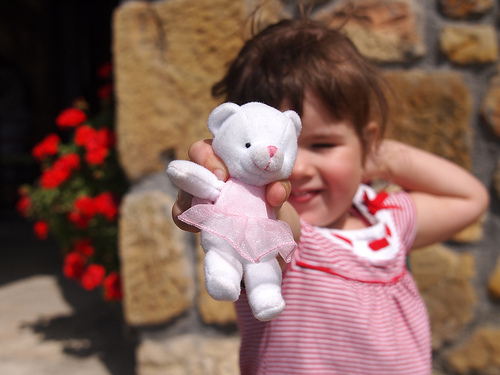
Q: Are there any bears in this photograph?
A: Yes, there is a bear.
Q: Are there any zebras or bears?
A: Yes, there is a bear.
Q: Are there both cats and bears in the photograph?
A: No, there is a bear but no cats.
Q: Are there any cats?
A: No, there are no cats.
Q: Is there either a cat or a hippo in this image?
A: No, there are no cats or hippos.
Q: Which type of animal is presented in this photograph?
A: The animal is a bear.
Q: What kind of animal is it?
A: The animal is a bear.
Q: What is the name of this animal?
A: This is a bear.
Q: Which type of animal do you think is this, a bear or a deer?
A: This is a bear.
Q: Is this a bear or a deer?
A: This is a bear.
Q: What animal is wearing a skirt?
A: The bear is wearing a skirt.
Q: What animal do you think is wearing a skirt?
A: The animal is a bear.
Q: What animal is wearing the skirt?
A: The animal is a bear.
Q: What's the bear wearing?
A: The bear is wearing a skirt.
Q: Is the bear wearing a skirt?
A: Yes, the bear is wearing a skirt.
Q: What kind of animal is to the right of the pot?
A: The animal is a bear.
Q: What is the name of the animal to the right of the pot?
A: The animal is a bear.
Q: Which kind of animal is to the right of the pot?
A: The animal is a bear.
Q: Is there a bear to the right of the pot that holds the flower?
A: Yes, there is a bear to the right of the pot.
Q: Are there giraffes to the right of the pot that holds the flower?
A: No, there is a bear to the right of the pot.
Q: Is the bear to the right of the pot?
A: Yes, the bear is to the right of the pot.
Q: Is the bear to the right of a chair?
A: No, the bear is to the right of the pot.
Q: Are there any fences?
A: No, there are no fences.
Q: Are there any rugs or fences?
A: No, there are no fences or rugs.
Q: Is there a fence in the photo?
A: No, there are no fences.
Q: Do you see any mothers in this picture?
A: No, there are no mothers.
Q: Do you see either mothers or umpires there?
A: No, there are no mothers or umpires.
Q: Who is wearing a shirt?
A: The girl is wearing a shirt.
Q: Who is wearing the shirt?
A: The girl is wearing a shirt.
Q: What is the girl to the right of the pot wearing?
A: The girl is wearing a shirt.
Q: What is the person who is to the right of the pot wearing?
A: The girl is wearing a shirt.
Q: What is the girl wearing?
A: The girl is wearing a shirt.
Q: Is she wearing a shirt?
A: Yes, the girl is wearing a shirt.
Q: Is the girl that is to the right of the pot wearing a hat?
A: No, the girl is wearing a shirt.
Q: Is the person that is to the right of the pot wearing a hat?
A: No, the girl is wearing a shirt.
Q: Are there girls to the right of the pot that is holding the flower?
A: Yes, there is a girl to the right of the pot.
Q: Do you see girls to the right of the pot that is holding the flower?
A: Yes, there is a girl to the right of the pot.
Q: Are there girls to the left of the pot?
A: No, the girl is to the right of the pot.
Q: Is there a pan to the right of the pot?
A: No, there is a girl to the right of the pot.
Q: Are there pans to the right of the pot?
A: No, there is a girl to the right of the pot.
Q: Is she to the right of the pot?
A: Yes, the girl is to the right of the pot.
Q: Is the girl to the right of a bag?
A: No, the girl is to the right of the pot.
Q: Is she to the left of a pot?
A: No, the girl is to the right of a pot.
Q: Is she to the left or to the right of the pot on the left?
A: The girl is to the right of the pot.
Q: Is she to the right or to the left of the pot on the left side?
A: The girl is to the right of the pot.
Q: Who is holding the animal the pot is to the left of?
A: The girl is holding the bear.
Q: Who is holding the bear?
A: The girl is holding the bear.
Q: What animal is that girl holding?
A: The girl is holding the bear.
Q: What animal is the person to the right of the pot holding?
A: The girl is holding the bear.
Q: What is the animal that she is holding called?
A: The animal is a bear.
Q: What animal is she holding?
A: The girl is holding the bear.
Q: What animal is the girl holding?
A: The girl is holding the bear.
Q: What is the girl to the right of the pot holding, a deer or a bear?
A: The girl is holding a bear.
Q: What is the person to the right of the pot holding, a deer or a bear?
A: The girl is holding a bear.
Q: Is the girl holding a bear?
A: Yes, the girl is holding a bear.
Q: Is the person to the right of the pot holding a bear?
A: Yes, the girl is holding a bear.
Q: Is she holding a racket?
A: No, the girl is holding a bear.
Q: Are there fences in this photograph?
A: No, there are no fences.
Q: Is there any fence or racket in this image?
A: No, there are no fences or rackets.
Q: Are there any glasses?
A: No, there are no glasses.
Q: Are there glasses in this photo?
A: No, there are no glasses.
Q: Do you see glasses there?
A: No, there are no glasses.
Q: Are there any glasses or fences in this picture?
A: No, there are no glasses or fences.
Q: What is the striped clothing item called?
A: The clothing item is a shirt.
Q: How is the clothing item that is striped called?
A: The clothing item is a shirt.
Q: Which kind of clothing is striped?
A: The clothing is a shirt.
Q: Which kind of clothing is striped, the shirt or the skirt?
A: The shirt is striped.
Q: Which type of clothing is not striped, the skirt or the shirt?
A: The skirt is not striped.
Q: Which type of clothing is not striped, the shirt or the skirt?
A: The skirt is not striped.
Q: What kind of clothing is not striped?
A: The clothing is a skirt.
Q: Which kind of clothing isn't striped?
A: The clothing is a skirt.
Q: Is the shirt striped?
A: Yes, the shirt is striped.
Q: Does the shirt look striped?
A: Yes, the shirt is striped.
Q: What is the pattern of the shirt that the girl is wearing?
A: The shirt is striped.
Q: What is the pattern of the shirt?
A: The shirt is striped.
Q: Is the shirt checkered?
A: No, the shirt is striped.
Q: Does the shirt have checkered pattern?
A: No, the shirt is striped.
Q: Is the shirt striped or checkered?
A: The shirt is striped.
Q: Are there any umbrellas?
A: No, there are no umbrellas.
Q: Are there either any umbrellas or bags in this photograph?
A: No, there are no umbrellas or bags.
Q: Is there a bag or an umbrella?
A: No, there are no umbrellas or bags.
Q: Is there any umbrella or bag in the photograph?
A: No, there are no umbrellas or bags.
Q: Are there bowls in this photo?
A: No, there are no bowls.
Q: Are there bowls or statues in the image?
A: No, there are no bowls or statues.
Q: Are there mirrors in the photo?
A: No, there are no mirrors.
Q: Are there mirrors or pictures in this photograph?
A: No, there are no mirrors or pictures.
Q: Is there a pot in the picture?
A: Yes, there is a pot.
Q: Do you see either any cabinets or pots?
A: Yes, there is a pot.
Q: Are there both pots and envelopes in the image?
A: No, there is a pot but no envelopes.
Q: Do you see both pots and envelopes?
A: No, there is a pot but no envelopes.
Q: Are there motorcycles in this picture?
A: No, there are no motorcycles.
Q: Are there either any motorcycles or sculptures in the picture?
A: No, there are no motorcycles or sculptures.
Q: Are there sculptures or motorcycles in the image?
A: No, there are no motorcycles or sculptures.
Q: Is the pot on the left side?
A: Yes, the pot is on the left of the image.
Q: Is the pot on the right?
A: No, the pot is on the left of the image.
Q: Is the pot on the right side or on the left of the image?
A: The pot is on the left of the image.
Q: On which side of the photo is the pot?
A: The pot is on the left of the image.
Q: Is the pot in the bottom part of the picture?
A: Yes, the pot is in the bottom of the image.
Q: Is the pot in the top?
A: No, the pot is in the bottom of the image.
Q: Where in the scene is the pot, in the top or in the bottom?
A: The pot is in the bottom of the image.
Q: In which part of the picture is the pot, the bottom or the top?
A: The pot is in the bottom of the image.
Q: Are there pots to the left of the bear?
A: Yes, there is a pot to the left of the bear.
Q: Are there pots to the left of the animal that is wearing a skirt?
A: Yes, there is a pot to the left of the bear.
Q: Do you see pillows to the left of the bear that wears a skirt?
A: No, there is a pot to the left of the bear.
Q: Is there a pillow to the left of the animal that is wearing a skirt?
A: No, there is a pot to the left of the bear.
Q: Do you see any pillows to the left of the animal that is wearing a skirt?
A: No, there is a pot to the left of the bear.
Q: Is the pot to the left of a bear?
A: Yes, the pot is to the left of a bear.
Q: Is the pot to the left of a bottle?
A: No, the pot is to the left of a bear.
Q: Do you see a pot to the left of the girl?
A: Yes, there is a pot to the left of the girl.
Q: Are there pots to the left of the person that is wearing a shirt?
A: Yes, there is a pot to the left of the girl.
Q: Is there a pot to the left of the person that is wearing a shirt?
A: Yes, there is a pot to the left of the girl.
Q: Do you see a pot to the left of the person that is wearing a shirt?
A: Yes, there is a pot to the left of the girl.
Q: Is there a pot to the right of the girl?
A: No, the pot is to the left of the girl.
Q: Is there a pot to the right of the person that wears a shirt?
A: No, the pot is to the left of the girl.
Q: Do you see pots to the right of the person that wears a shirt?
A: No, the pot is to the left of the girl.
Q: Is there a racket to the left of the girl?
A: No, there is a pot to the left of the girl.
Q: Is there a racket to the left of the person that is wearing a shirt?
A: No, there is a pot to the left of the girl.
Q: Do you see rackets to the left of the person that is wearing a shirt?
A: No, there is a pot to the left of the girl.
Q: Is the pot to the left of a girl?
A: Yes, the pot is to the left of a girl.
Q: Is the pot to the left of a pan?
A: No, the pot is to the left of a girl.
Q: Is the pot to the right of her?
A: No, the pot is to the left of the girl.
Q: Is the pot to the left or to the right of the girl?
A: The pot is to the left of the girl.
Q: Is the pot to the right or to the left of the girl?
A: The pot is to the left of the girl.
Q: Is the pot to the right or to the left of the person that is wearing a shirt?
A: The pot is to the left of the girl.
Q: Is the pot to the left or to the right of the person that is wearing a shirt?
A: The pot is to the left of the girl.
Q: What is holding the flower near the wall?
A: The pot is holding the flower.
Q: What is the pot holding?
A: The pot is holding the flower.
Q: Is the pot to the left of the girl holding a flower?
A: Yes, the pot is holding a flower.